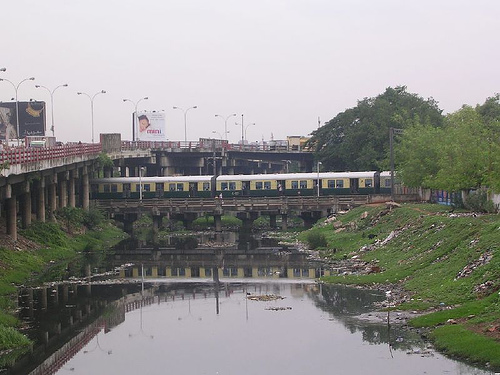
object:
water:
[0, 225, 497, 374]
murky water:
[1, 223, 494, 373]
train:
[73, 161, 450, 230]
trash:
[449, 249, 496, 274]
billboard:
[131, 109, 168, 140]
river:
[35, 233, 481, 373]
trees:
[307, 85, 447, 175]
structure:
[3, 129, 103, 232]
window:
[166, 182, 183, 192]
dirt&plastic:
[247, 290, 278, 302]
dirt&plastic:
[41, 264, 136, 284]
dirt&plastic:
[198, 231, 235, 251]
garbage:
[325, 202, 392, 232]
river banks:
[299, 194, 497, 355]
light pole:
[75, 85, 109, 147]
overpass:
[3, 122, 385, 173]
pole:
[131, 110, 137, 155]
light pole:
[32, 80, 72, 142]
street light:
[207, 109, 239, 139]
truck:
[23, 136, 58, 154]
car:
[55, 140, 65, 149]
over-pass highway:
[0, 144, 162, 218]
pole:
[183, 102, 187, 143]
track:
[108, 189, 387, 229]